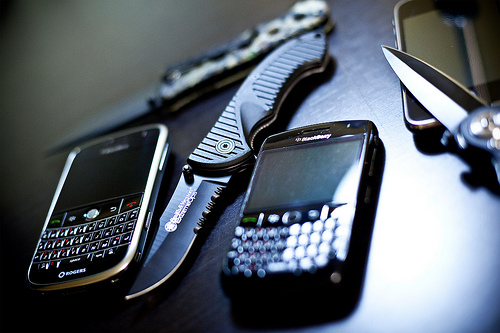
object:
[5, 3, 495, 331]
table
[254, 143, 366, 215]
screen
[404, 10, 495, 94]
screen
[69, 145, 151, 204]
screen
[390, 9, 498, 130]
phone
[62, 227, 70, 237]
button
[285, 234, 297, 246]
white button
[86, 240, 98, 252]
white button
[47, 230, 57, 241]
white button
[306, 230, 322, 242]
white button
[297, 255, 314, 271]
white button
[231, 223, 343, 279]
buttons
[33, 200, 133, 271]
buttons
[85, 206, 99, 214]
button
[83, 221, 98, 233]
button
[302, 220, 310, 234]
button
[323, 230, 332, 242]
button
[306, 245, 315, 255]
button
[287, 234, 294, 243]
button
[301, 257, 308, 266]
button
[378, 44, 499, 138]
blade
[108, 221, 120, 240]
button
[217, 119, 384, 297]
cellphone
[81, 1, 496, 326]
desk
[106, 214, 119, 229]
button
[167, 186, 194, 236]
words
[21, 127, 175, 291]
cellphone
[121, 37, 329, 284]
blade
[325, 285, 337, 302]
motorcycle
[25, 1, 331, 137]
knife